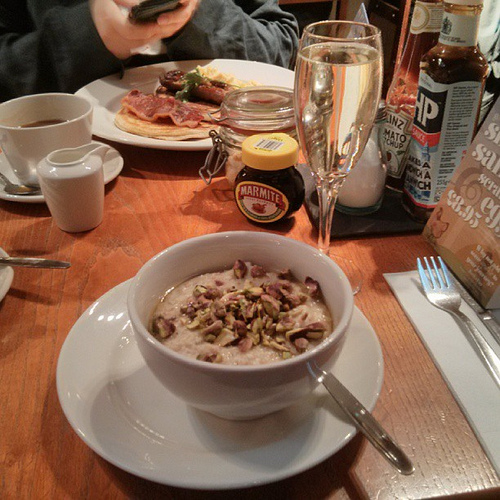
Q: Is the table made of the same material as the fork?
A: No, the table is made of wood and the fork is made of metal.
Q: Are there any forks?
A: Yes, there is a fork.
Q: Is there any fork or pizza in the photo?
A: Yes, there is a fork.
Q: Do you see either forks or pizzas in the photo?
A: Yes, there is a fork.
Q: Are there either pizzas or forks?
A: Yes, there is a fork.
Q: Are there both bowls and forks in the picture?
A: Yes, there are both a fork and a bowl.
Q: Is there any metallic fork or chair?
A: Yes, there is a metal fork.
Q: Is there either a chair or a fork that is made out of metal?
A: Yes, the fork is made of metal.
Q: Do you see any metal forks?
A: Yes, there is a metal fork.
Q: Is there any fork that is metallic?
A: Yes, there is a fork that is metallic.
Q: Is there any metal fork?
A: Yes, there is a fork that is made of metal.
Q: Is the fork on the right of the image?
A: Yes, the fork is on the right of the image.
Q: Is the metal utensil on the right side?
A: Yes, the fork is on the right of the image.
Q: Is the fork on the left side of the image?
A: No, the fork is on the right of the image.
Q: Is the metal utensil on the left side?
A: No, the fork is on the right of the image.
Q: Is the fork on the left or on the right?
A: The fork is on the right of the image.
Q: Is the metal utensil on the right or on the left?
A: The fork is on the right of the image.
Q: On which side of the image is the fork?
A: The fork is on the right of the image.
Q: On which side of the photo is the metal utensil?
A: The fork is on the right of the image.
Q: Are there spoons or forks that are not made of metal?
A: No, there is a fork but it is made of metal.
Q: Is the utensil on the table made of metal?
A: Yes, the fork is made of metal.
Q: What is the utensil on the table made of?
A: The fork is made of metal.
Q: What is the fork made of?
A: The fork is made of metal.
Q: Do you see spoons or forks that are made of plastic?
A: No, there is a fork but it is made of metal.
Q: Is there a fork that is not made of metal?
A: No, there is a fork but it is made of metal.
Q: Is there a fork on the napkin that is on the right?
A: Yes, there is a fork on the napkin.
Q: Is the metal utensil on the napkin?
A: Yes, the fork is on the napkin.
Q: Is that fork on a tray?
A: No, the fork is on the napkin.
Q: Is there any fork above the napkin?
A: Yes, there is a fork above the napkin.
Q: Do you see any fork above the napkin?
A: Yes, there is a fork above the napkin.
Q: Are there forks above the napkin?
A: Yes, there is a fork above the napkin.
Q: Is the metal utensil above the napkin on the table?
A: Yes, the fork is above the napkin.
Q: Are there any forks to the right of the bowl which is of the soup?
A: Yes, there is a fork to the right of the bowl.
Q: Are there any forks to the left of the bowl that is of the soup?
A: No, the fork is to the right of the bowl.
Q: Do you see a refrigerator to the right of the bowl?
A: No, there is a fork to the right of the bowl.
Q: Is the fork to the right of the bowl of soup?
A: Yes, the fork is to the right of the bowl.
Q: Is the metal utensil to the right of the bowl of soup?
A: Yes, the fork is to the right of the bowl.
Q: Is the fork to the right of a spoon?
A: No, the fork is to the right of the bowl.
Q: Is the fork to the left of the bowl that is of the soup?
A: No, the fork is to the right of the bowl.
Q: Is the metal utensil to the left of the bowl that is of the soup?
A: No, the fork is to the right of the bowl.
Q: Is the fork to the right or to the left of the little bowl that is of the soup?
A: The fork is to the right of the bowl.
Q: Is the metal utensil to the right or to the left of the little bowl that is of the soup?
A: The fork is to the right of the bowl.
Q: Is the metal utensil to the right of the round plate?
A: Yes, the fork is to the right of the plate.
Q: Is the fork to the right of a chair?
A: No, the fork is to the right of the plate.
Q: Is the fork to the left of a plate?
A: No, the fork is to the right of a plate.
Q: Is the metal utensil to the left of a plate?
A: No, the fork is to the right of a plate.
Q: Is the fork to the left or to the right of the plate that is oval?
A: The fork is to the right of the plate.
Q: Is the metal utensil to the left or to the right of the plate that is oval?
A: The fork is to the right of the plate.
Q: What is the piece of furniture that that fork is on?
A: The piece of furniture is a table.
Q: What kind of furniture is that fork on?
A: The fork is on the table.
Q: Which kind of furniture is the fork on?
A: The fork is on the table.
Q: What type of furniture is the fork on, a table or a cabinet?
A: The fork is on a table.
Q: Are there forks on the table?
A: Yes, there is a fork on the table.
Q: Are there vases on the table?
A: No, there is a fork on the table.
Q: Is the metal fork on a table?
A: Yes, the fork is on a table.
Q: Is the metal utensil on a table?
A: Yes, the fork is on a table.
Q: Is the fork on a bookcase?
A: No, the fork is on a table.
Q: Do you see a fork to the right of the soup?
A: Yes, there is a fork to the right of the soup.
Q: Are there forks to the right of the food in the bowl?
A: Yes, there is a fork to the right of the soup.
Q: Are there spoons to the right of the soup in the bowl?
A: No, there is a fork to the right of the soup.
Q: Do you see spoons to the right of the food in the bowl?
A: No, there is a fork to the right of the soup.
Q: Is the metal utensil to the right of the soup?
A: Yes, the fork is to the right of the soup.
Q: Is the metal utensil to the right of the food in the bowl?
A: Yes, the fork is to the right of the soup.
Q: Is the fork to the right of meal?
A: No, the fork is to the right of the soup.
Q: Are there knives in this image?
A: Yes, there is a knife.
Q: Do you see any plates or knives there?
A: Yes, there is a knife.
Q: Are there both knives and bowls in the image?
A: Yes, there are both a knife and a bowl.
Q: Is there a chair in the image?
A: No, there are no chairs.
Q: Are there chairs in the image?
A: No, there are no chairs.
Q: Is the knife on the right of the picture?
A: Yes, the knife is on the right of the image.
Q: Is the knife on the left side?
A: No, the knife is on the right of the image.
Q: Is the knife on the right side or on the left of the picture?
A: The knife is on the right of the image.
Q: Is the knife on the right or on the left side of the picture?
A: The knife is on the right of the image.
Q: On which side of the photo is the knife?
A: The knife is on the right of the image.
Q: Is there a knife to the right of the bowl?
A: Yes, there is a knife to the right of the bowl.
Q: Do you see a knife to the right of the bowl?
A: Yes, there is a knife to the right of the bowl.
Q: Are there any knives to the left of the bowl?
A: No, the knife is to the right of the bowl.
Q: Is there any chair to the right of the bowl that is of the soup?
A: No, there is a knife to the right of the bowl.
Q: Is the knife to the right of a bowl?
A: Yes, the knife is to the right of a bowl.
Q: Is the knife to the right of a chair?
A: No, the knife is to the right of a bowl.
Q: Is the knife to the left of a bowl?
A: No, the knife is to the right of a bowl.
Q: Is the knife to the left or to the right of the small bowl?
A: The knife is to the right of the bowl.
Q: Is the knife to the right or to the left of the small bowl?
A: The knife is to the right of the bowl.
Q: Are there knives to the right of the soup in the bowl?
A: Yes, there is a knife to the right of the soup.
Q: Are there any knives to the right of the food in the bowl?
A: Yes, there is a knife to the right of the soup.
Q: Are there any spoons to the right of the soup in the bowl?
A: No, there is a knife to the right of the soup.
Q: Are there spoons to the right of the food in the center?
A: No, there is a knife to the right of the soup.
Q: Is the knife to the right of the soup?
A: Yes, the knife is to the right of the soup.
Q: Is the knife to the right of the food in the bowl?
A: Yes, the knife is to the right of the soup.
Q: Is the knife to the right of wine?
A: No, the knife is to the right of the soup.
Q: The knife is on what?
A: The knife is on the napkin.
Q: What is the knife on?
A: The knife is on the napkin.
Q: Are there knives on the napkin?
A: Yes, there is a knife on the napkin.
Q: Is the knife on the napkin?
A: Yes, the knife is on the napkin.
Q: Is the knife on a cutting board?
A: No, the knife is on the napkin.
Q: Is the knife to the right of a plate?
A: Yes, the knife is to the right of a plate.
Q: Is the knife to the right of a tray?
A: No, the knife is to the right of a plate.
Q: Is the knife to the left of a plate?
A: No, the knife is to the right of a plate.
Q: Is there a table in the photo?
A: Yes, there is a table.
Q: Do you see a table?
A: Yes, there is a table.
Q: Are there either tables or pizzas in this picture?
A: Yes, there is a table.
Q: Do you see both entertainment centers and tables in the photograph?
A: No, there is a table but no entertainment centers.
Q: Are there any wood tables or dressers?
A: Yes, there is a wood table.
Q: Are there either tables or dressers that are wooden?
A: Yes, the table is wooden.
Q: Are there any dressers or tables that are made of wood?
A: Yes, the table is made of wood.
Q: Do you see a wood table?
A: Yes, there is a table that is made of wood.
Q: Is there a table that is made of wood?
A: Yes, there is a table that is made of wood.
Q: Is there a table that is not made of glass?
A: Yes, there is a table that is made of wood.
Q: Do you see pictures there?
A: No, there are no pictures.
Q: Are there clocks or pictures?
A: No, there are no pictures or clocks.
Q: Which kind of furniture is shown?
A: The furniture is a table.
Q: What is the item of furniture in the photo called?
A: The piece of furniture is a table.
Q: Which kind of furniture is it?
A: The piece of furniture is a table.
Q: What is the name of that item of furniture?
A: That is a table.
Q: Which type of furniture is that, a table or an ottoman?
A: That is a table.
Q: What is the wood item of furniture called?
A: The piece of furniture is a table.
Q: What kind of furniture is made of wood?
A: The furniture is a table.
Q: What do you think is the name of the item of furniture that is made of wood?
A: The piece of furniture is a table.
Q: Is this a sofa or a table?
A: This is a table.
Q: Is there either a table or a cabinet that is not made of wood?
A: No, there is a table but it is made of wood.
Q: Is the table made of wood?
A: Yes, the table is made of wood.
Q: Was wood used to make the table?
A: Yes, the table is made of wood.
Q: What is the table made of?
A: The table is made of wood.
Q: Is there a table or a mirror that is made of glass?
A: No, there is a table but it is made of wood.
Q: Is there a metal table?
A: No, there is a table but it is made of wood.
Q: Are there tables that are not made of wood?
A: No, there is a table but it is made of wood.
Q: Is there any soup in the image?
A: Yes, there is soup.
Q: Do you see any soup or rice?
A: Yes, there is soup.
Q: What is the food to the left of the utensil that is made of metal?
A: The food is soup.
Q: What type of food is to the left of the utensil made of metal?
A: The food is soup.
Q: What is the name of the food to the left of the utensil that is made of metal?
A: The food is soup.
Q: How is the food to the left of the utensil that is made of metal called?
A: The food is soup.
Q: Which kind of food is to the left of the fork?
A: The food is soup.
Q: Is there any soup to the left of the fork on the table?
A: Yes, there is soup to the left of the fork.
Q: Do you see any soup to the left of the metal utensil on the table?
A: Yes, there is soup to the left of the fork.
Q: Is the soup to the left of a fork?
A: Yes, the soup is to the left of a fork.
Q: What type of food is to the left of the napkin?
A: The food is soup.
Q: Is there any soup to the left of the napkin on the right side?
A: Yes, there is soup to the left of the napkin.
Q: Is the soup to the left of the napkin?
A: Yes, the soup is to the left of the napkin.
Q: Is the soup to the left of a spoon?
A: No, the soup is to the left of the napkin.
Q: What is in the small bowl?
A: The soup is in the bowl.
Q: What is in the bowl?
A: The soup is in the bowl.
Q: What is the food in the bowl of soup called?
A: The food is soup.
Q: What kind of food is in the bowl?
A: The food is soup.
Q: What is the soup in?
A: The soup is in the bowl.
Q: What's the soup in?
A: The soup is in the bowl.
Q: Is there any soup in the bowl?
A: Yes, there is soup in the bowl.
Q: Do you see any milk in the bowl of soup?
A: No, there is soup in the bowl.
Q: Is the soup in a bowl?
A: Yes, the soup is in a bowl.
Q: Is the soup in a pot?
A: No, the soup is in a bowl.